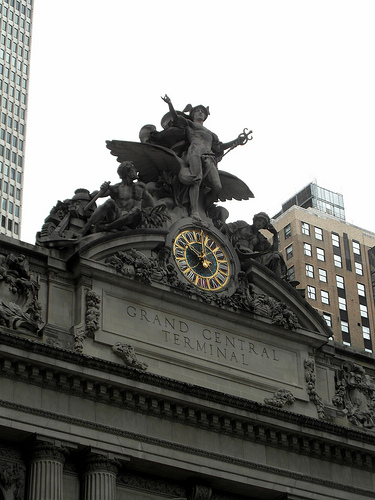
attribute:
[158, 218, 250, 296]
clock — Gold 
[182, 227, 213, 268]
hands — black, gold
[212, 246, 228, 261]
numeral — roman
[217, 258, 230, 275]
numeral — roman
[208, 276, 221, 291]
numeral — roman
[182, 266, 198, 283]
numeral — roman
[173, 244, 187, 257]
numeral — roman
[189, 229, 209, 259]
hands — black, gold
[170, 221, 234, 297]
clock — gold, small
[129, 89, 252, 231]
statue — man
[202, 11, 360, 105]
sky — white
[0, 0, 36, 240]
skyscraper — tall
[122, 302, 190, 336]
grand — carved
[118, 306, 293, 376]
letters — carved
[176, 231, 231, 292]
filigree — gold